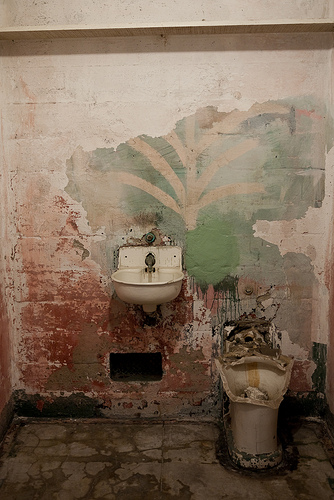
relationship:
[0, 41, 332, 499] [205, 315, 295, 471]
bathroom with toliet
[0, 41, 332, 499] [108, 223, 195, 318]
bathroom with sink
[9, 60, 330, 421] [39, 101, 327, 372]
wall with design